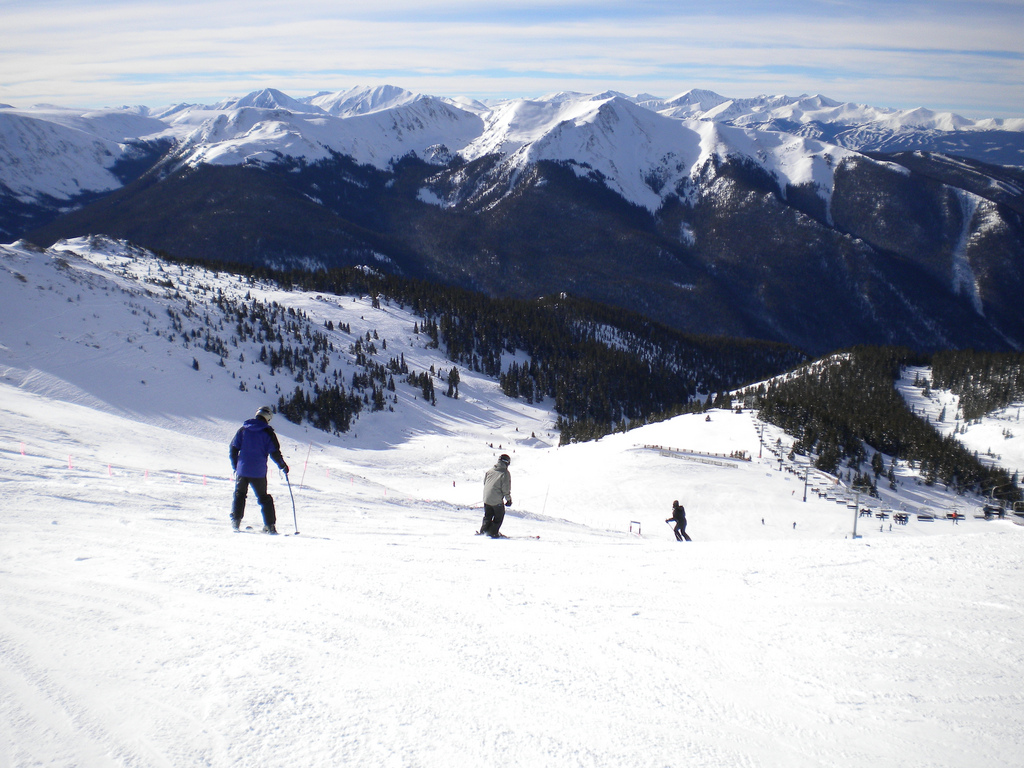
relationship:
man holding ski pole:
[228, 405, 288, 535] [282, 469, 304, 528]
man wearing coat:
[228, 405, 288, 535] [484, 461, 514, 506]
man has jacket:
[480, 454, 512, 539] [482, 465, 513, 504]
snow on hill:
[0, 83, 1024, 217] [15, 230, 992, 753]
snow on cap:
[11, 93, 990, 178] [11, 93, 992, 208]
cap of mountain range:
[11, 93, 992, 208] [0, 83, 1024, 351]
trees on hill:
[360, 351, 408, 423] [253, 251, 521, 453]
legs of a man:
[231, 465, 271, 524] [214, 387, 308, 480]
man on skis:
[228, 405, 288, 535] [216, 504, 310, 554]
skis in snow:
[216, 504, 310, 554] [116, 499, 497, 733]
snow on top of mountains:
[0, 83, 1024, 217] [99, 80, 983, 541]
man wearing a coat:
[477, 441, 538, 485] [471, 458, 541, 541]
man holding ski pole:
[203, 385, 281, 470] [285, 473, 301, 534]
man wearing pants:
[480, 454, 512, 539] [469, 497, 515, 537]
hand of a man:
[261, 448, 314, 487] [214, 387, 292, 468]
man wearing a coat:
[228, 405, 288, 535] [228, 418, 286, 478]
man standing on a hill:
[480, 454, 512, 539] [441, 532, 822, 764]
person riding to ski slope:
[661, 493, 700, 535] [572, 515, 918, 682]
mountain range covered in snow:
[36, 44, 974, 451] [354, 57, 709, 178]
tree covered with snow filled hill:
[777, 409, 821, 498] [654, 363, 888, 616]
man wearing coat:
[228, 405, 288, 535] [228, 418, 286, 478]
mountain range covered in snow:
[0, 83, 1024, 351] [497, 117, 655, 206]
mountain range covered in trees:
[0, 83, 1024, 351] [704, 167, 823, 234]